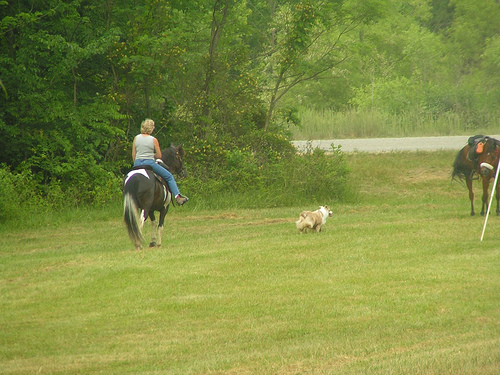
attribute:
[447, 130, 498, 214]
horse — brown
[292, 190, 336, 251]
dog — brown, white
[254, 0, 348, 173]
tree — filled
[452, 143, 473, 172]
tail — black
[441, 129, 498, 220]
horse — brown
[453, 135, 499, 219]
horse — brown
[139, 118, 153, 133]
hair — blonde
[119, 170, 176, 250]
horse — black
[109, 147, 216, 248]
horse — black, white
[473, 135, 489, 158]
bed roll — orange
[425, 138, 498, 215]
horse — looking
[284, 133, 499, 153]
road — black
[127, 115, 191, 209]
person — riding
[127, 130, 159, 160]
top — gray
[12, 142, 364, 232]
vegatation — green